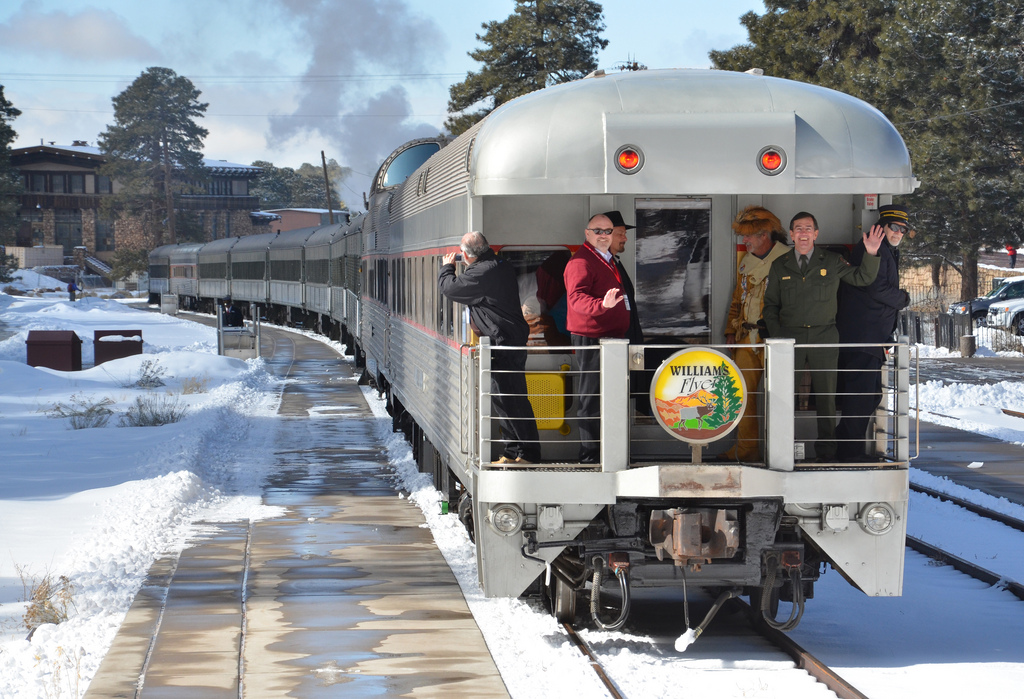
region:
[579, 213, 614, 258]
the head of a man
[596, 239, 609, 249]
the mouth of a man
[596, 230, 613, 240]
the nose of a man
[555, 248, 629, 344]
the jacket of a man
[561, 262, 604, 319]
the arm of a man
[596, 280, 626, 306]
the fingers of a man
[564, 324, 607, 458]
the pants of a man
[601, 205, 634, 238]
the hat of a man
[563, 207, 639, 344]
Man is wearing glasses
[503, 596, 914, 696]
Snow on the tracks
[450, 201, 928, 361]
Six people are shown on the end of the train.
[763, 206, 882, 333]
Man with brown jacket is waving.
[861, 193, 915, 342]
Man on the far right is wearing a hat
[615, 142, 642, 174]
Red light on a train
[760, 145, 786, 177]
Red light on a train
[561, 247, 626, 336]
Man wearing a red jacket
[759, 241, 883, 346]
Man wearing a green jacket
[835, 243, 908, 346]
Man wearing a black jacket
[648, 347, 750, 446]
Colorful sign on the train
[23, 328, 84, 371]
Trash bin in the snow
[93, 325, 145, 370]
Trash bin in the snow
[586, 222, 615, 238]
Man wearing sun glasses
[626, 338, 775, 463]
Yellow circle on the front of the train.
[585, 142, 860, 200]
Two red lights on the top of the train.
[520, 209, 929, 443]
Group of people standing on the train.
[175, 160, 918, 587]
Large silver train on the tracks.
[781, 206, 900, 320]
Man wearing a green suit waving to someone.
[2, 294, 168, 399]
Two black trash cans in the snow.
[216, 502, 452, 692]
Puddles of water on the concrete sidewalk.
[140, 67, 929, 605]
silver and red train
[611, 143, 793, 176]
two red front lights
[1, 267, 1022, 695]
lot beautiful white snow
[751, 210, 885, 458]
man with green uniform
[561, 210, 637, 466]
man with red jacket and blue pants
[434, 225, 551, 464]
man with blue jacket and pants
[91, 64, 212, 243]
a tall pine tree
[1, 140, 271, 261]
brick house in back ground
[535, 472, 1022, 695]
a metal and wood rail tracks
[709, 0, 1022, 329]
bunch of trees on right side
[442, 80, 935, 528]
people behind the train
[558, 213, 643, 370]
man wears a red coat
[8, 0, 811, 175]
The cloudy sky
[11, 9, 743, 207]
A cloudy sky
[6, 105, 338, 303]
The building in the background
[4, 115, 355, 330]
A building in the background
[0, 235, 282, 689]
The snow to the left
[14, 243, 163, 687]
A pile of snow to the left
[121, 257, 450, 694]
The concrete sidewalk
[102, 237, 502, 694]
A concrete sidewalk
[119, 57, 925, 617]
The silver train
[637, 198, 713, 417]
A window on a vehicle.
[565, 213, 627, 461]
A person is standing up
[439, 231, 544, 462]
A person is standing up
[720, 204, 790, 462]
A person is standing up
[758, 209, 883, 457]
A person is waving at something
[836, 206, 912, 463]
A person is standing up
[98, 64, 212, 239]
A tree in a city.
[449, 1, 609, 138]
A tree in a city.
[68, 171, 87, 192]
A window on a building.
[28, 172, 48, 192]
A window on a building.